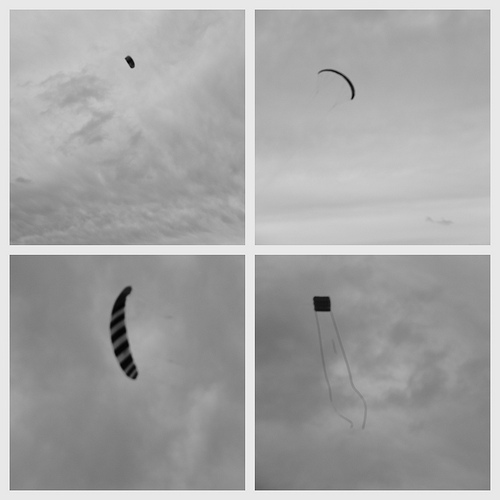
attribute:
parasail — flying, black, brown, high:
[99, 278, 150, 383]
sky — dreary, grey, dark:
[8, 257, 244, 491]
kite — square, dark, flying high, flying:
[298, 283, 373, 436]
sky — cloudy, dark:
[368, 268, 459, 383]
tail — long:
[308, 311, 371, 432]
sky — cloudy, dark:
[8, 10, 244, 243]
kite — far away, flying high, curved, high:
[123, 51, 139, 71]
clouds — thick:
[51, 25, 216, 234]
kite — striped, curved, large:
[95, 270, 160, 389]